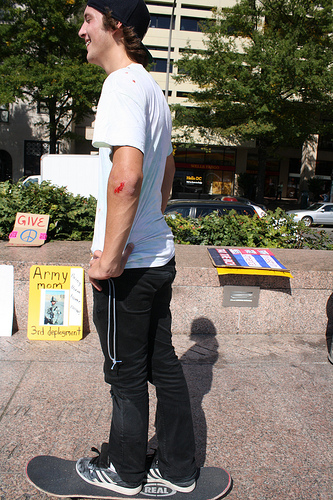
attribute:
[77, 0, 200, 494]
man — standing, smiling, light skinned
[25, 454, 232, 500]
skateboard — black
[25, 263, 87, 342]
sign — yellow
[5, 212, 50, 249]
sign — cardboard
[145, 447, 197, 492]
shoe — adidas, athletic, black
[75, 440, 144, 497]
shoe — adidas, athletic, black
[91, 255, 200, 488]
pants — black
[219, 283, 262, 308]
vent — metal, silver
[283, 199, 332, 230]
car — silver, parked, grey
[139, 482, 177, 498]
logo — white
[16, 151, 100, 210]
truck — white, large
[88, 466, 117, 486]
stripes — white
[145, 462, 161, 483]
stripes — white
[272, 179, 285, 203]
person — far, standing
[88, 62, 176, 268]
shirt — white